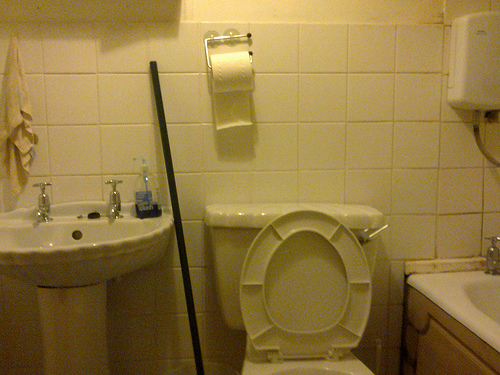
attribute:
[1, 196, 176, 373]
sink — white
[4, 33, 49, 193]
towel — hanging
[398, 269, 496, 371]
tub — big, white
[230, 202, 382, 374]
toilet — white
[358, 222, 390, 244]
handle — metal, flush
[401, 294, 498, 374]
bathtub frame — wooden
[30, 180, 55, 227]
faucet — chrome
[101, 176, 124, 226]
faucet — chrome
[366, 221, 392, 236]
handle — chrome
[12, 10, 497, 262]
tile — ceramic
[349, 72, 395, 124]
tile — white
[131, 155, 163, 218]
bottle — plastic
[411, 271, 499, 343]
bathtub — white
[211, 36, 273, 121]
tissue paper — roll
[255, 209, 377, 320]
lid — up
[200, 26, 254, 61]
paper holder — chrome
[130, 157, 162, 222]
dispenser — soap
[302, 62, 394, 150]
wall — tiled